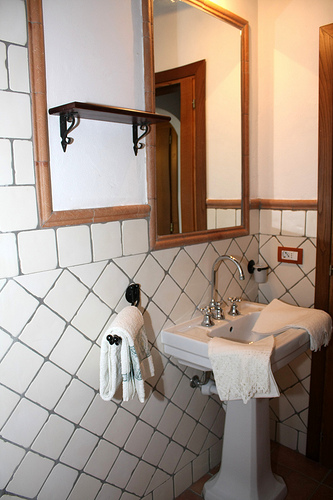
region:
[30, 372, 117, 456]
the tiles are white and gray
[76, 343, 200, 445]
the towel is hanging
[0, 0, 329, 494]
this is a bathroom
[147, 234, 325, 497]
this is a sink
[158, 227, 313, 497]
this is a pedestal sink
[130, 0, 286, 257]
this is a mirror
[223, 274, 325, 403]
towel on the sink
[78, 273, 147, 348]
this is a towel holder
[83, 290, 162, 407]
towel on the rack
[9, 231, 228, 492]
tile on the wall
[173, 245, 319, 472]
the sink is white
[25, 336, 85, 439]
the tiles are white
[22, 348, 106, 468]
the tiles are white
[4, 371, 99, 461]
the tiles are white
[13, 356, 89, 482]
the tiles are white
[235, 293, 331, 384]
towels on the sink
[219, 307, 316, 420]
towels on the sink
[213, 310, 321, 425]
towels on the sink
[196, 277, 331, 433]
towels on the sink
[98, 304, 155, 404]
a hanging white printed towel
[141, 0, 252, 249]
a wall mounted vanity mirror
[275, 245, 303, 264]
an electrical wall outlet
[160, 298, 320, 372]
a white porcelain bathroom sink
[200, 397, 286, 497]
a white porcelain bathroom sink pedestal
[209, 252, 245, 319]
a chrome bathroom faucet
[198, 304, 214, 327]
a chrome water faucet knob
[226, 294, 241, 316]
a chrome water faucet knob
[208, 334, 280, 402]
a draped white towel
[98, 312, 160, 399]
The towel on the bar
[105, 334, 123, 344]
The bar is black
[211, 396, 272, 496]
The base of the sink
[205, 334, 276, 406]
The towel hanging on the left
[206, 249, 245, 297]
The chrome faucet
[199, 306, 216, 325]
The hot water knob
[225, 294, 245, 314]
The cold water knob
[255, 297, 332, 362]
The towel hanging on the right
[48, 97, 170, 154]
shelf mounted on wall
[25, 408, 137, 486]
White tiles on wall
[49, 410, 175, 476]
White tiles mounted on wall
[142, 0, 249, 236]
mirror mounted on wall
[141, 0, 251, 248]
mirror in frame on wall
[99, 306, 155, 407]
white towel on rack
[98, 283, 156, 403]
white towel on wall mounted rack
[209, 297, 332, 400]
two white towel on bathroom basin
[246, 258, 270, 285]
cup holder on wall